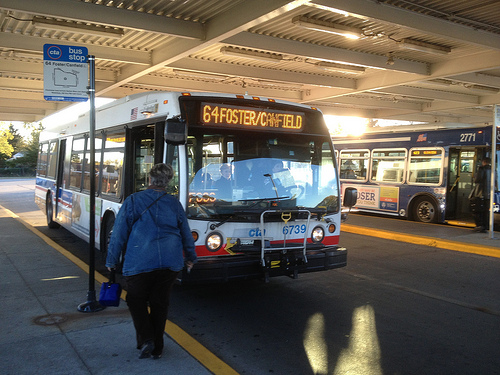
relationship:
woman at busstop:
[98, 154, 201, 360] [40, 41, 104, 313]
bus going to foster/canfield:
[38, 89, 360, 273] [203, 102, 309, 133]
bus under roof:
[34, 90, 358, 288] [4, 2, 498, 126]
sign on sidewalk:
[40, 41, 104, 313] [7, 209, 186, 373]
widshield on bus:
[191, 129, 333, 211] [38, 89, 360, 273]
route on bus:
[203, 102, 309, 133] [38, 89, 360, 273]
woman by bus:
[98, 154, 201, 360] [38, 89, 360, 273]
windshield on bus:
[191, 129, 333, 211] [38, 89, 360, 273]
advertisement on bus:
[346, 185, 411, 207] [38, 89, 360, 273]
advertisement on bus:
[346, 185, 411, 207] [334, 134, 499, 225]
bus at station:
[38, 89, 360, 273] [3, 1, 500, 374]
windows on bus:
[40, 136, 125, 194] [38, 89, 360, 273]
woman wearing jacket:
[98, 154, 201, 360] [110, 186, 193, 272]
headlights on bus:
[308, 220, 329, 246] [38, 89, 360, 273]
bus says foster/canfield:
[38, 89, 360, 273] [203, 102, 309, 133]